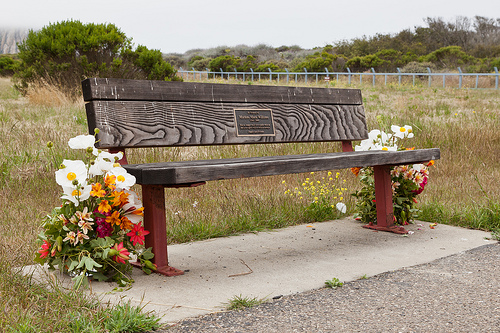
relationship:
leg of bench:
[140, 180, 186, 274] [81, 77, 440, 277]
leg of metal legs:
[362, 164, 410, 233] [133, 174, 419, 275]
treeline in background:
[166, 16, 497, 73] [4, 2, 496, 84]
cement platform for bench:
[173, 217, 420, 300] [74, 61, 444, 279]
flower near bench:
[37, 133, 152, 279] [81, 77, 440, 277]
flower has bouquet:
[37, 133, 152, 279] [32, 132, 156, 279]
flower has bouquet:
[66, 132, 97, 154] [32, 132, 156, 279]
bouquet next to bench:
[32, 132, 156, 279] [81, 77, 440, 277]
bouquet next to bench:
[358, 129, 426, 241] [81, 77, 440, 277]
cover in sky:
[88, 6, 475, 77] [190, 9, 257, 36]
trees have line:
[0, 16, 500, 103] [185, 56, 320, 79]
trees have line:
[163, 16, 499, 89] [185, 56, 320, 79]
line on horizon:
[185, 56, 320, 79] [9, 47, 492, 87]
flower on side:
[37, 133, 152, 279] [95, 83, 172, 261]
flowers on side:
[355, 123, 436, 243] [357, 83, 406, 223]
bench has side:
[81, 77, 440, 277] [95, 83, 172, 261]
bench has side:
[81, 77, 440, 277] [357, 83, 406, 223]